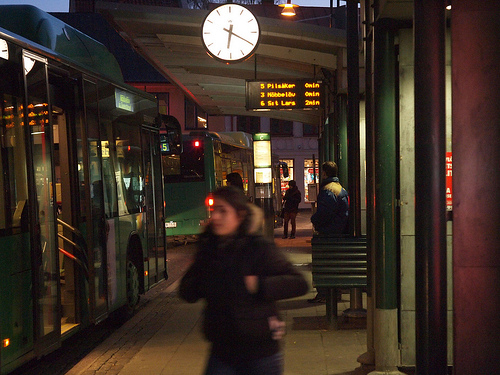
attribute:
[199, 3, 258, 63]
clock — lit up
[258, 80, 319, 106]
writing — yellow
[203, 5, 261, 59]
clock — white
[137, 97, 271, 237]
bus — city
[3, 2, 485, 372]
picture — night time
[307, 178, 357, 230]
jacket — blue, yellow, ski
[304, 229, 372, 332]
bench — bus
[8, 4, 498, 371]
terminal — bus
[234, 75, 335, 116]
display — digital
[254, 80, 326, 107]
times — arrival, departure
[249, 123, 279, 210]
display — informational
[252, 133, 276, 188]
routes — bus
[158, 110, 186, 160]
mirror — buses, rear view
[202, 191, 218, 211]
lights — buses, brake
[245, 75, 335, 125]
schedule — bus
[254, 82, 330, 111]
times — arrival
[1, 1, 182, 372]
bus — green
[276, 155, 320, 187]
lights — on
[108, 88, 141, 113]
destination — lit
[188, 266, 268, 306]
hands — warm, jacket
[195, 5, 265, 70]
clock — hanging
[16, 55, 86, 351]
door — open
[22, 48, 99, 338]
door — open